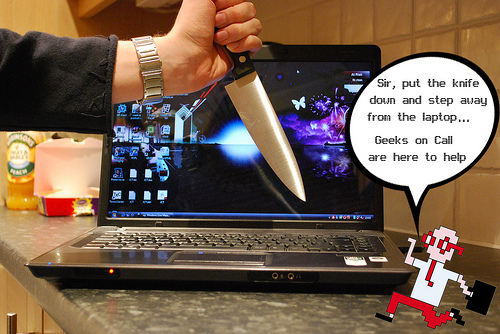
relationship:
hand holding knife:
[165, 0, 264, 97] [217, 47, 311, 204]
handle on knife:
[212, 32, 259, 84] [217, 47, 311, 204]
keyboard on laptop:
[72, 224, 393, 260] [24, 43, 414, 287]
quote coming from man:
[343, 58, 465, 195] [354, 224, 458, 332]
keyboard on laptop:
[80, 230, 388, 254] [24, 43, 414, 287]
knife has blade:
[208, 9, 313, 206] [224, 68, 311, 201]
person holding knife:
[7, 14, 203, 119] [211, 86, 322, 181]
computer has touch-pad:
[38, 25, 448, 295] [165, 251, 271, 263]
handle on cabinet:
[4, 310, 18, 332] [2, 265, 62, 332]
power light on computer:
[107, 267, 114, 273] [22, 40, 420, 290]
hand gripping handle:
[165, 0, 264, 96] [212, 32, 255, 79]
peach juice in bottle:
[5, 176, 36, 206] [3, 128, 44, 210]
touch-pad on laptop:
[165, 247, 271, 268] [24, 43, 414, 287]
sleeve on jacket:
[13, 5, 149, 161] [0, 21, 125, 140]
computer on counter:
[23, 43, 416, 291] [2, 204, 497, 332]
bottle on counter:
[5, 125, 46, 210] [2, 204, 497, 332]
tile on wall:
[340, 0, 375, 45] [258, 4, 499, 248]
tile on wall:
[455, 0, 497, 26] [258, 4, 499, 248]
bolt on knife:
[228, 40, 274, 88] [189, 26, 352, 238]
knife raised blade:
[208, 9, 313, 206] [220, 62, 316, 205]